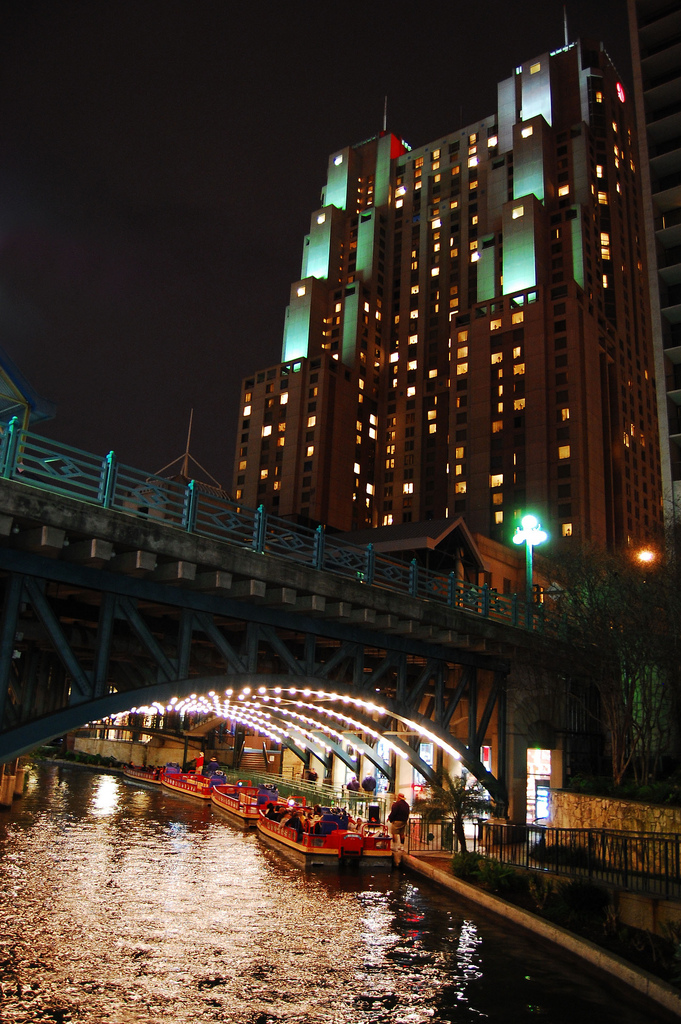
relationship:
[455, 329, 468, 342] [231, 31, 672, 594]
window on building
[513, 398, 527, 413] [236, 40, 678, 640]
window on building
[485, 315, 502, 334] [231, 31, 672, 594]
window on building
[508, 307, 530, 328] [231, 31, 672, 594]
window on building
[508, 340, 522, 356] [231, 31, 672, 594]
window on building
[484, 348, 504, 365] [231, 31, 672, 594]
window on building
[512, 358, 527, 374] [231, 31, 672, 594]
window on building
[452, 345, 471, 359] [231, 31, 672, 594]
window on building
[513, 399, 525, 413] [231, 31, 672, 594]
window on building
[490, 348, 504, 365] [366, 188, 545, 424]
window on building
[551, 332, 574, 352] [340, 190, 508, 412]
window on building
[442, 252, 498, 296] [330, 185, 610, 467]
window on building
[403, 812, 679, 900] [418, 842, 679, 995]
gate near sidewalk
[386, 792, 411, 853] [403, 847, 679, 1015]
man standing on sidewalk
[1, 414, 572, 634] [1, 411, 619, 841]
gate on bridge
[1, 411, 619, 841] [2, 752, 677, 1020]
bridge over river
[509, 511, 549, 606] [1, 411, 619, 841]
light on bridge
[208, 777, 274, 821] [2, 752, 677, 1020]
boat in river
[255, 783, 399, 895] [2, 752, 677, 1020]
boat in a river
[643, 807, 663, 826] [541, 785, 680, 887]
rock in a wall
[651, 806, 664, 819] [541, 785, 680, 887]
rock in a wall